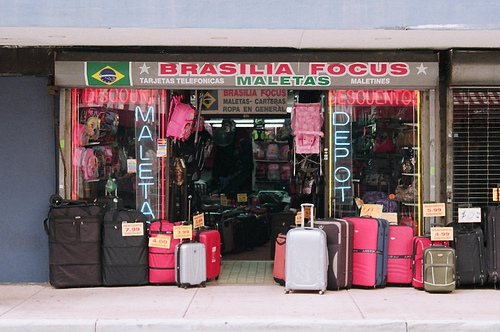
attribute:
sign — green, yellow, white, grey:
[57, 59, 440, 87]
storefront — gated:
[50, 65, 431, 288]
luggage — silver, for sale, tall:
[283, 221, 332, 298]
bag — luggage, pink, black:
[350, 221, 391, 292]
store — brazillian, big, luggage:
[8, 47, 483, 330]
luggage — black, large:
[108, 211, 140, 292]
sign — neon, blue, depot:
[330, 101, 367, 209]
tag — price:
[433, 225, 457, 240]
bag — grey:
[180, 245, 209, 286]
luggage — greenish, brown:
[421, 249, 463, 293]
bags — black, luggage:
[48, 207, 148, 290]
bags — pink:
[346, 218, 414, 286]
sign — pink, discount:
[86, 91, 156, 107]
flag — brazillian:
[84, 62, 130, 89]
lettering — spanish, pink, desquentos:
[330, 89, 418, 104]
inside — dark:
[171, 118, 295, 205]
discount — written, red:
[79, 87, 168, 103]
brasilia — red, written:
[158, 63, 299, 80]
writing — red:
[161, 62, 412, 80]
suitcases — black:
[45, 201, 450, 277]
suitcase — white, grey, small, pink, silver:
[179, 243, 208, 287]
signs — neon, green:
[133, 111, 352, 208]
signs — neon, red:
[84, 91, 406, 98]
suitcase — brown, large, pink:
[307, 209, 357, 291]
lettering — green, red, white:
[158, 63, 403, 81]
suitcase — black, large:
[446, 217, 500, 277]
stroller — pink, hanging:
[286, 101, 317, 167]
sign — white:
[449, 201, 483, 222]